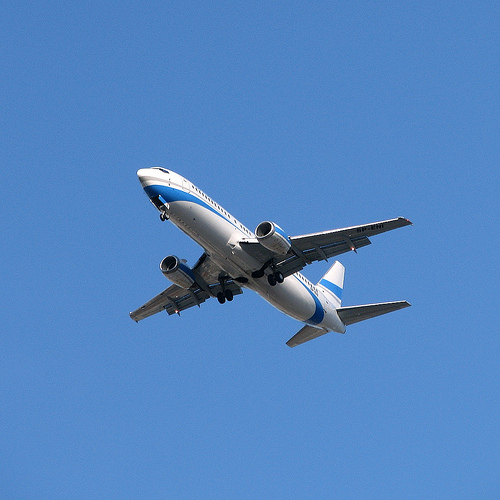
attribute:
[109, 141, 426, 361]
plane — air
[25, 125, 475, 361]
plane — cockpit 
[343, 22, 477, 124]
brown trunk — blue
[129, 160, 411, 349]
airplane — striped, blue, white, mid air, triped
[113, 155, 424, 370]
airplane — blue, white, striped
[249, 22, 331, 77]
sky — blue, white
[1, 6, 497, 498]
sky — clear, blue 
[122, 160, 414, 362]
plane — wing 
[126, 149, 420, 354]
plane — wing 